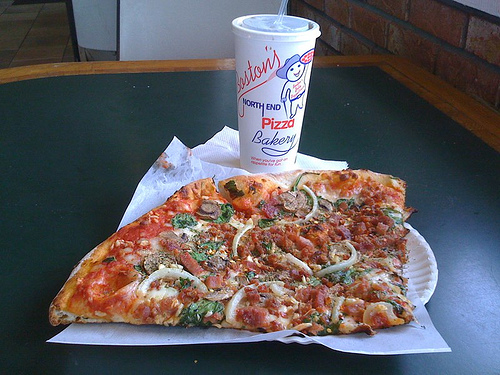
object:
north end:
[239, 97, 280, 119]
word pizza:
[259, 118, 296, 131]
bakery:
[252, 130, 297, 157]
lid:
[231, 12, 323, 42]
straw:
[273, 0, 289, 30]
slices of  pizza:
[49, 169, 416, 337]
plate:
[125, 171, 441, 344]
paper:
[47, 125, 453, 356]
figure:
[276, 53, 306, 118]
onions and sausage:
[226, 222, 293, 263]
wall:
[415, 0, 498, 76]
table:
[1, 66, 498, 373]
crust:
[48, 239, 108, 325]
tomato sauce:
[80, 264, 141, 316]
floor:
[1, 0, 63, 61]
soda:
[246, 15, 311, 33]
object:
[116, 0, 289, 60]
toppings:
[234, 303, 270, 327]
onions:
[141, 267, 211, 312]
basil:
[184, 296, 225, 326]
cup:
[231, 2, 321, 171]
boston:
[235, 50, 282, 99]